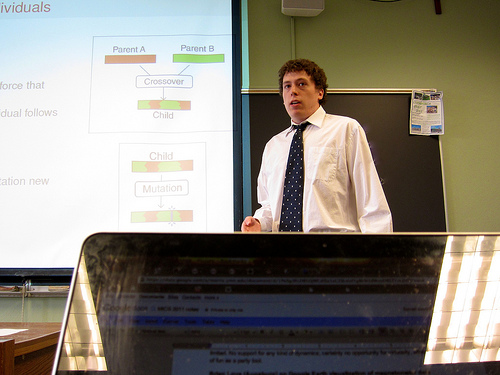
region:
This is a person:
[247, 42, 402, 274]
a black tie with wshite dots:
[280, 124, 312, 231]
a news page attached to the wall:
[406, 89, 444, 137]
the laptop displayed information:
[82, 240, 438, 372]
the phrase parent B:
[178, 42, 215, 54]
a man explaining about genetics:
[251, 59, 389, 237]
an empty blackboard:
[387, 152, 447, 233]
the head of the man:
[277, 60, 324, 120]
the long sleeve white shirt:
[311, 116, 386, 238]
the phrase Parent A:
[111, 44, 148, 53]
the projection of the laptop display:
[1, 41, 233, 229]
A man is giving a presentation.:
[5, 0, 492, 371]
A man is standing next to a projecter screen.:
[0, 1, 401, 232]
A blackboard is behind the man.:
[245, 85, 443, 230]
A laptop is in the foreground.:
[56, 232, 496, 372]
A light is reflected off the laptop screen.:
[426, 237, 497, 368]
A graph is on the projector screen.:
[91, 30, 231, 231]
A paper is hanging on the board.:
[408, 90, 441, 136]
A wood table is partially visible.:
[0, 321, 52, 372]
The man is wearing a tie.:
[275, 125, 316, 231]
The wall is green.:
[348, 23, 496, 82]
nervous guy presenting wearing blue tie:
[242, 55, 396, 231]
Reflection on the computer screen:
[83, 232, 498, 374]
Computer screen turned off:
[52, 231, 498, 373]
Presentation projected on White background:
[0, 0, 239, 271]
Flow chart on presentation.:
[93, 35, 235, 218]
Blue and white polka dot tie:
[275, 123, 311, 230]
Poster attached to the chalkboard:
[406, 85, 457, 130]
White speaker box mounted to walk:
[278, 0, 334, 18]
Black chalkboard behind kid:
[243, 91, 448, 230]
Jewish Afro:
[276, 56, 331, 96]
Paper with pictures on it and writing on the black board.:
[408, 88, 445, 137]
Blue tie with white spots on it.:
[280, 121, 312, 231]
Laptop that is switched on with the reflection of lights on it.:
[51, 225, 498, 372]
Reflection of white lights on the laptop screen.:
[424, 234, 499, 363]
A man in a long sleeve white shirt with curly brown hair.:
[240, 59, 394, 232]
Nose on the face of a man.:
[287, 85, 299, 97]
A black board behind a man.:
[241, 85, 449, 232]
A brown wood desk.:
[0, 320, 62, 373]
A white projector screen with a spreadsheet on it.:
[1, 0, 253, 269]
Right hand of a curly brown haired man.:
[241, 215, 261, 235]